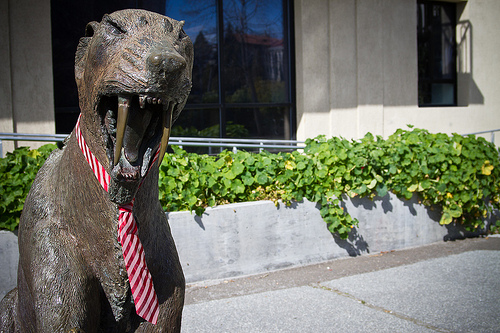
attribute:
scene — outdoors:
[4, 6, 498, 271]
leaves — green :
[458, 164, 485, 196]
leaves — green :
[349, 128, 388, 171]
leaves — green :
[299, 158, 348, 210]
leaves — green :
[246, 139, 314, 208]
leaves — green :
[227, 155, 272, 193]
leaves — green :
[188, 147, 226, 217]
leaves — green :
[180, 161, 220, 207]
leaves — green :
[4, 147, 27, 177]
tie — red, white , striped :
[60, 104, 175, 330]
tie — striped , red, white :
[75, 104, 173, 330]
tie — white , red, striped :
[72, 110, 166, 330]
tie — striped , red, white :
[71, 104, 188, 330]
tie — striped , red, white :
[69, 99, 170, 330]